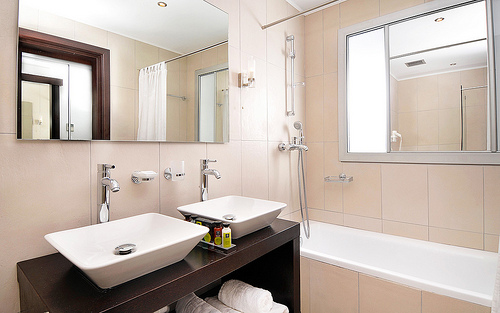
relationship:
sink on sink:
[176, 193, 288, 240] [176, 193, 288, 240]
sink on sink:
[44, 210, 210, 289] [176, 193, 288, 240]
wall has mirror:
[4, 9, 322, 235] [11, 1, 233, 140]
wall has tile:
[4, 9, 322, 235] [221, 145, 280, 193]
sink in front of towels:
[39, 216, 205, 285] [206, 288, 290, 313]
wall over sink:
[4, 9, 322, 235] [39, 216, 205, 285]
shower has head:
[273, 32, 332, 260] [281, 113, 308, 140]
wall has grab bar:
[4, 9, 322, 235] [317, 167, 362, 195]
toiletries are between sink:
[186, 218, 234, 253] [176, 193, 288, 240]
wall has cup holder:
[4, 9, 322, 235] [162, 163, 197, 184]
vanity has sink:
[12, 221, 306, 307] [176, 193, 288, 240]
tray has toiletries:
[184, 235, 235, 258] [186, 218, 234, 253]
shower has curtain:
[273, 32, 332, 260] [138, 66, 173, 146]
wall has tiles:
[4, 9, 322, 235] [380, 178, 499, 226]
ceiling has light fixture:
[36, 5, 228, 52] [152, 1, 175, 15]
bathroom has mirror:
[5, 4, 498, 309] [11, 1, 233, 140]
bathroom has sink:
[5, 4, 498, 309] [176, 193, 288, 240]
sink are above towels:
[176, 193, 288, 240] [206, 288, 290, 313]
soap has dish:
[138, 167, 160, 180] [134, 171, 157, 186]